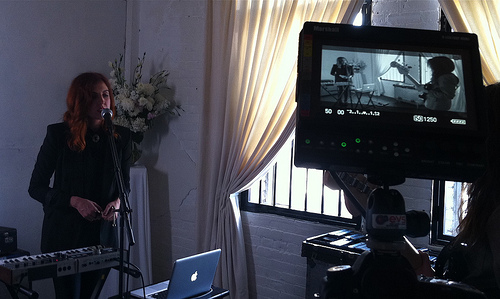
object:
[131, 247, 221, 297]
laptop computer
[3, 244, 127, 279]
keyboard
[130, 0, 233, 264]
wall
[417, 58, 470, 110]
woman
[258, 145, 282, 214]
bars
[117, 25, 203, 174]
corner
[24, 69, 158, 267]
woman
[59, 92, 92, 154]
hair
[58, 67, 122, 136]
head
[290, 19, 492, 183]
camera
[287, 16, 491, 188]
monitor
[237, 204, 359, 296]
wall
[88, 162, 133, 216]
stand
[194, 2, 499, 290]
curtain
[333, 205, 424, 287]
xylophone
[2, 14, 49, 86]
walls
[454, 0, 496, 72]
curtains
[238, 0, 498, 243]
window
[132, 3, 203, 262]
brick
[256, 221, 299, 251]
brick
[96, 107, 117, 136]
microphone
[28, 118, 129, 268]
jacket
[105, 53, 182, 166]
bouquet